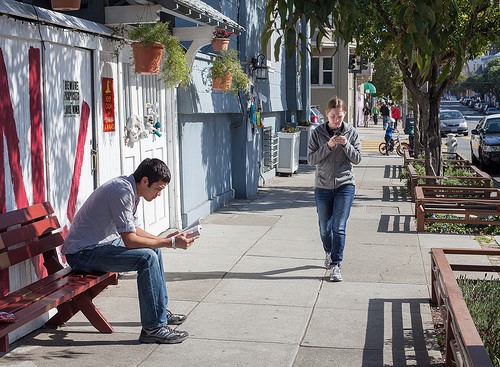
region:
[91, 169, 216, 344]
a man sitting on the bench reading a book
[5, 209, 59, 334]
a red bench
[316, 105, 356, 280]
a woman walking and texting at the same time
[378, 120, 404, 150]
a kid riding his bike in the background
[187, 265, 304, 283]
the woman's shadow while she walks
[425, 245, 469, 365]
a fence surrounding a tree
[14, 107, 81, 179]
a white and red wall of the building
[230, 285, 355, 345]
concrete pavement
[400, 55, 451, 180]
a tree in the background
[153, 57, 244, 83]
plants hanging in the background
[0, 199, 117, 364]
Red wooden bench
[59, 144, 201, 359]
Man reading a book on bench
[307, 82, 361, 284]
Lady walking looking at phone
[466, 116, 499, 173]
Black and white car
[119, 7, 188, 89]
Flower pot hanging from building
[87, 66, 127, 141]
Red and yellow sign on building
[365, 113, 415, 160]
Boy in blue shirt on bike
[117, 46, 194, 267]
White double doors with windows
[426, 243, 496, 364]
Small wooden fence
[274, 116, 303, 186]
Gray and white flower pot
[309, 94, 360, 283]
woman texting walking on sidewalk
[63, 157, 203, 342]
boy on bench reading a book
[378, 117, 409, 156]
kid in white helmet on bicycle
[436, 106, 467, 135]
gray car parked at the curb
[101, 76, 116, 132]
red sign on the wall with yellow lettering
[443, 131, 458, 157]
white fire hydrant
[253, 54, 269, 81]
light that is hanging from blue building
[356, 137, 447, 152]
yellow lines on the street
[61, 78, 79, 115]
white sign on door with black lettering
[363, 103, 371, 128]
man in black shirt and khaki pants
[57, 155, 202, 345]
Young man sitting on bench reading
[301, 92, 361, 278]
Young woman walking on sidewalk viewing cell phone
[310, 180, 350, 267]
Blue jeans on young woman on sidewalk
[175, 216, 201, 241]
Book being read by young man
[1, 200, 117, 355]
Red bench supporting young man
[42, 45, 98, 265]
White door with red stripe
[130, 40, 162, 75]
Hanging red flower pot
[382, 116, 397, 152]
Small boy on a bike in background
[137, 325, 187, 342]
Black and white shoe worn by young man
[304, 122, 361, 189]
Gray shirt on young woman on sidewalk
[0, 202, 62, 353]
Red bench on the ground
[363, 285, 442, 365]
Black fence shadow on the ground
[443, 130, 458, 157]
White fire hydrant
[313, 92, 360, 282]
Woman walking and checking her phone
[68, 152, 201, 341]
Man sitting and reading a book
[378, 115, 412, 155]
Boy wearing blue and a white helmet on a bike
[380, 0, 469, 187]
Tree growing on a side walk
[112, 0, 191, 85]
Hanging plant with green leaves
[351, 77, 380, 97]
Greenish blue awning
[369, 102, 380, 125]
Man in a green shirt walking